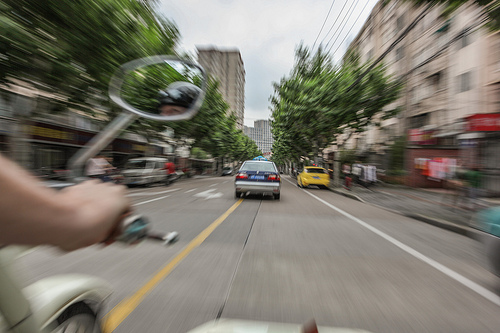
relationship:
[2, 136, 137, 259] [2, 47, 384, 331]
rider on scooter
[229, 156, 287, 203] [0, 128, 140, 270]
car in front of rider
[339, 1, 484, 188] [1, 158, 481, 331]
building on street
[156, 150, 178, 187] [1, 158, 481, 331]
person walking across street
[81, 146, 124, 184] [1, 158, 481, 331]
person walking across street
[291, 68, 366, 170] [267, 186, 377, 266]
trees lining street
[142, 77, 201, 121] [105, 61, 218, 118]
reflection in mirror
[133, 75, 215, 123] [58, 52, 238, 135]
helmet in mirror